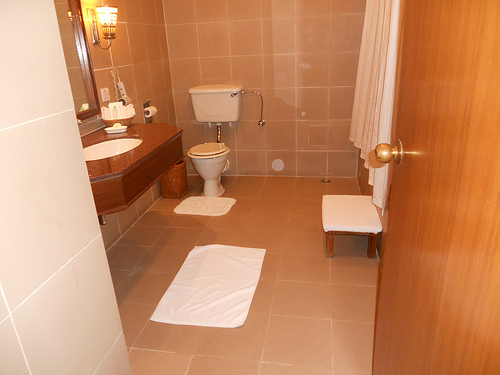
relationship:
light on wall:
[88, 7, 123, 53] [124, 26, 163, 71]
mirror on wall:
[43, 18, 102, 123] [124, 26, 163, 71]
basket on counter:
[98, 103, 146, 145] [145, 125, 189, 180]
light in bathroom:
[88, 7, 123, 53] [65, 6, 433, 346]